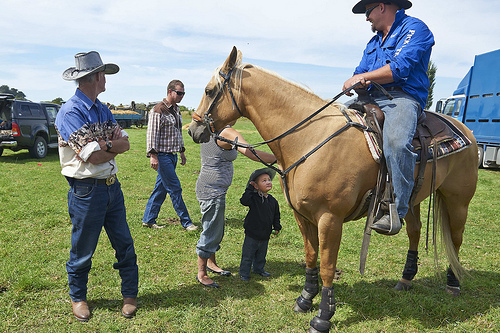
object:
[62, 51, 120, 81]
grey hat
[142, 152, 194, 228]
jeans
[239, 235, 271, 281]
blue jeans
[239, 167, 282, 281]
child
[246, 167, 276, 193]
cowboy hat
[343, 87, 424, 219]
blue jeans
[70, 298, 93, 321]
boot